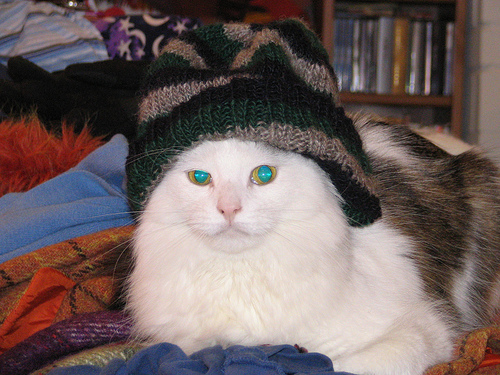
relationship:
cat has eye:
[174, 119, 463, 320] [184, 160, 287, 192]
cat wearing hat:
[174, 119, 463, 320] [140, 26, 361, 173]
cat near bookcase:
[174, 119, 463, 320] [349, 6, 489, 152]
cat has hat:
[174, 119, 463, 320] [140, 26, 361, 173]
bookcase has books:
[349, 6, 489, 152] [362, 31, 438, 79]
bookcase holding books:
[349, 6, 489, 152] [362, 31, 438, 79]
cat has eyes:
[174, 119, 463, 320] [186, 158, 289, 238]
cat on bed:
[174, 119, 463, 320] [13, 53, 137, 300]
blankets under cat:
[163, 342, 237, 375] [174, 119, 463, 320]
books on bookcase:
[362, 31, 438, 79] [349, 6, 489, 152]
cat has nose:
[174, 119, 463, 320] [216, 196, 234, 218]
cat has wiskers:
[174, 119, 463, 320] [281, 221, 341, 253]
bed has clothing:
[13, 53, 137, 300] [39, 177, 104, 233]